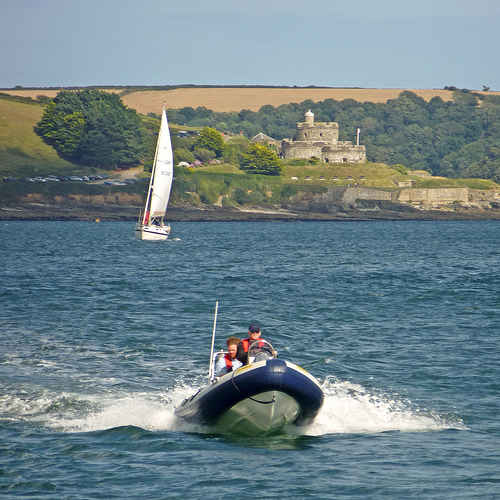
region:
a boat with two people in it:
[172, 300, 327, 440]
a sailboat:
[130, 102, 175, 242]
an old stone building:
[252, 108, 368, 165]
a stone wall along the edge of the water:
[276, 183, 498, 215]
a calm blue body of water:
[2, 216, 498, 498]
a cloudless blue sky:
[1, 1, 499, 88]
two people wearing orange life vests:
[214, 323, 274, 373]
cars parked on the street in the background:
[2, 171, 148, 187]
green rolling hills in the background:
[1, 84, 499, 171]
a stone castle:
[281, 106, 367, 164]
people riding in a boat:
[213, 321, 275, 376]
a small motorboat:
[173, 354, 322, 439]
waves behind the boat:
[68, 372, 455, 437]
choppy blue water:
[0, 216, 499, 498]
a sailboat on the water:
[135, 98, 172, 238]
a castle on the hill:
[278, 110, 365, 163]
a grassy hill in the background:
[0, 90, 499, 210]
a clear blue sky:
[0, 0, 499, 92]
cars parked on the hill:
[3, 168, 137, 185]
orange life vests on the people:
[224, 338, 265, 372]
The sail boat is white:
[131, 102, 176, 244]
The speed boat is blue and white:
[171, 291, 326, 445]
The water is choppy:
[0, 216, 497, 498]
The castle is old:
[228, 107, 368, 166]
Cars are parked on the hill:
[0, 168, 135, 188]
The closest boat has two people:
[171, 292, 323, 440]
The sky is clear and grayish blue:
[0, 0, 498, 92]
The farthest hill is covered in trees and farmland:
[2, 86, 499, 178]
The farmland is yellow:
[1, 87, 498, 112]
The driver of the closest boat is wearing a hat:
[188, 289, 313, 442]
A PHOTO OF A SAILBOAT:
[129, 103, 187, 249]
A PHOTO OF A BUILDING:
[234, 99, 381, 169]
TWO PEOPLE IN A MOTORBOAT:
[169, 280, 340, 449]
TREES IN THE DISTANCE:
[368, 90, 495, 181]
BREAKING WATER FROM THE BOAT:
[321, 370, 473, 440]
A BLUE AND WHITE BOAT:
[162, 315, 334, 450]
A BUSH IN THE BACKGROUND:
[218, 137, 314, 184]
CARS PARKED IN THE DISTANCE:
[5, 171, 130, 189]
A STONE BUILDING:
[253, 106, 395, 166]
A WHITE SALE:
[142, 101, 187, 221]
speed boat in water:
[80, 274, 380, 474]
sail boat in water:
[137, 110, 188, 274]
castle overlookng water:
[274, 40, 412, 207]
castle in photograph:
[257, 114, 407, 171]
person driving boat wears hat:
[221, 291, 272, 362]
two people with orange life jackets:
[211, 312, 285, 380]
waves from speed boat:
[50, 344, 392, 452]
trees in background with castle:
[28, 74, 485, 172]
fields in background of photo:
[24, 52, 498, 144]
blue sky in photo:
[21, 5, 498, 127]